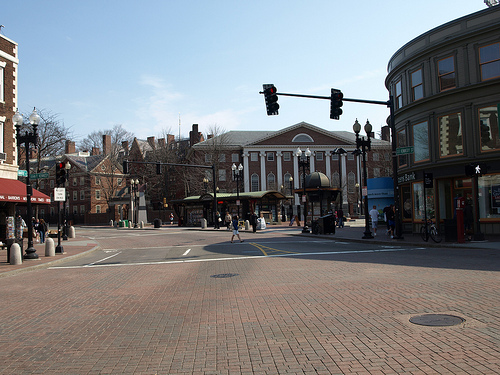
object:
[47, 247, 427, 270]
lines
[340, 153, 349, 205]
columns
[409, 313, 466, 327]
cover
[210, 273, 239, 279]
cover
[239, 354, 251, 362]
bricks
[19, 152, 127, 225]
building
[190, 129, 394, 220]
building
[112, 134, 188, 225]
building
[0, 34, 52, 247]
building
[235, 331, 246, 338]
bricks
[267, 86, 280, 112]
light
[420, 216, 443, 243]
bike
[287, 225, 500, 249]
sidewalk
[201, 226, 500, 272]
shadow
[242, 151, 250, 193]
column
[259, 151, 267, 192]
column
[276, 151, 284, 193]
column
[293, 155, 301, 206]
column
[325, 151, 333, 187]
column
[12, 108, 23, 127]
lights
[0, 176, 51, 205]
awning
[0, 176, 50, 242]
shop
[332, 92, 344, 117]
light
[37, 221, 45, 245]
person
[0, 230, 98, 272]
sidewalk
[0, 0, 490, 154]
sky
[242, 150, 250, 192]
pillar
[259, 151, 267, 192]
pillar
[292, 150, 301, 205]
pillar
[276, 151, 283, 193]
pillar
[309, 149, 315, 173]
pillar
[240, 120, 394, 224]
building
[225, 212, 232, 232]
woman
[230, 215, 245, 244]
pedestrian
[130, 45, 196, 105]
clouds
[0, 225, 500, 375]
road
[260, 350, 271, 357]
brick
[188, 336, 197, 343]
brick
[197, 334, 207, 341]
brick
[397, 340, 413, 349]
brick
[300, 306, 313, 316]
brick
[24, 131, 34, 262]
pole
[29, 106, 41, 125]
street light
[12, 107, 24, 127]
street light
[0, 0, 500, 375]
background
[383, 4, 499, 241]
building